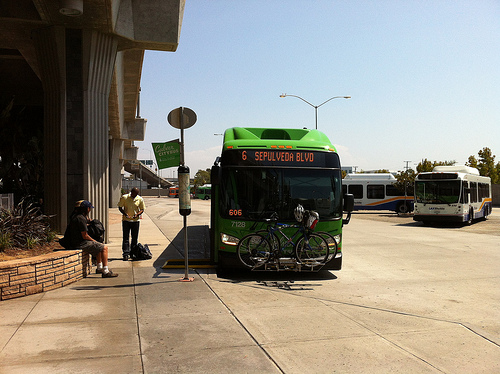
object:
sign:
[151, 138, 183, 168]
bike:
[234, 209, 329, 268]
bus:
[209, 127, 353, 269]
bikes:
[245, 211, 337, 267]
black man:
[115, 187, 143, 261]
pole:
[177, 129, 191, 278]